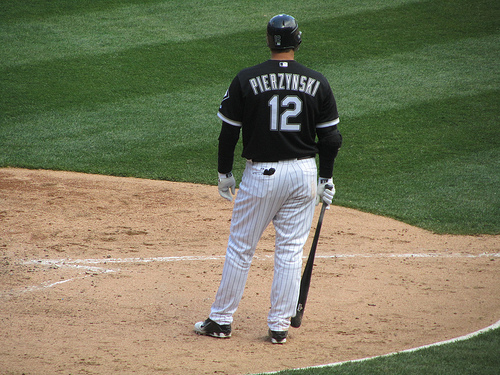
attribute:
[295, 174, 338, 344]
bat — black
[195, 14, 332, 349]
player — standing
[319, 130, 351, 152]
elbow — protected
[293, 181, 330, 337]
bat — black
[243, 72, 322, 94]
name — last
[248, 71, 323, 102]
letters — white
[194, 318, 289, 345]
cleats — baseball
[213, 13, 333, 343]
baseball player — pierzynski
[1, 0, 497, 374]
grass — green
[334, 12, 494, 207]
grass — green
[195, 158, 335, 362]
pants — white, striped, black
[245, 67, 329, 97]
letters — white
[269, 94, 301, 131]
numbers — 1 and 2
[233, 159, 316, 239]
baseball pants — pinstriped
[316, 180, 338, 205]
gloves — white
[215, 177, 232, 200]
gloves — white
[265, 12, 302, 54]
helmet — black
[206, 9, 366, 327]
player — baseball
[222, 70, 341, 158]
jersey — black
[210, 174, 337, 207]
gloves — white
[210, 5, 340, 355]
man — white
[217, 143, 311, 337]
pants — striped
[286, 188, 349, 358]
bat — black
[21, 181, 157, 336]
ground — dirt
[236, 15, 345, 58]
helmet — black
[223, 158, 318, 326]
pants — white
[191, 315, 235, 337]
shoe — black, white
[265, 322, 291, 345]
shoe — black, white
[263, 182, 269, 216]
stripe — black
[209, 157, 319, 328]
stripes — thin